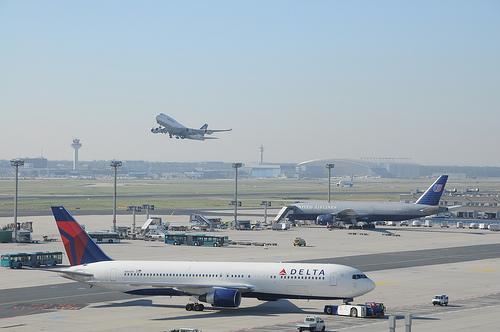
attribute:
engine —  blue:
[212, 289, 242, 308]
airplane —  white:
[48, 194, 385, 326]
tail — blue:
[417, 171, 448, 208]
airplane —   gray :
[274, 170, 456, 225]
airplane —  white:
[42, 204, 375, 308]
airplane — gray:
[287, 172, 449, 225]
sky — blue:
[308, 28, 451, 101]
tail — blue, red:
[46, 203, 115, 269]